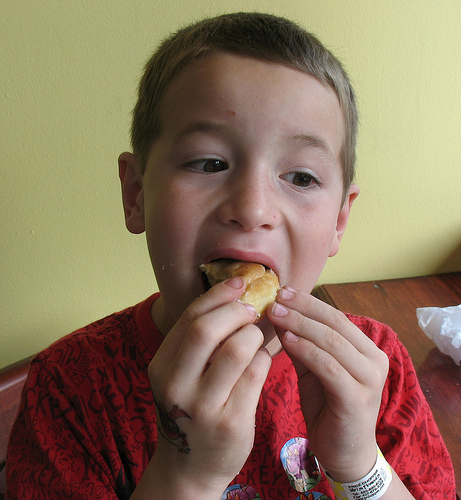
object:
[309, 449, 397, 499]
tag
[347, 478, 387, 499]
writing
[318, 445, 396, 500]
wrist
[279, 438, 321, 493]
sticker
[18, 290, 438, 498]
shirt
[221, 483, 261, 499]
sticker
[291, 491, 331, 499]
sticker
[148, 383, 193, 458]
artwork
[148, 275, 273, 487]
hand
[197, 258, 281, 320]
food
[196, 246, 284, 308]
mouth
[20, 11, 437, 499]
boy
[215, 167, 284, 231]
nose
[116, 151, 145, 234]
ear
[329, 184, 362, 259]
ear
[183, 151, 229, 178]
eye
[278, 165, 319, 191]
eye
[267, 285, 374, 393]
fingers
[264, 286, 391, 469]
hand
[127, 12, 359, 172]
hair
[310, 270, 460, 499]
table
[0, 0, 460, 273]
wall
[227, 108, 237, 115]
scratch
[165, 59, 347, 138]
forehead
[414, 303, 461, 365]
bag